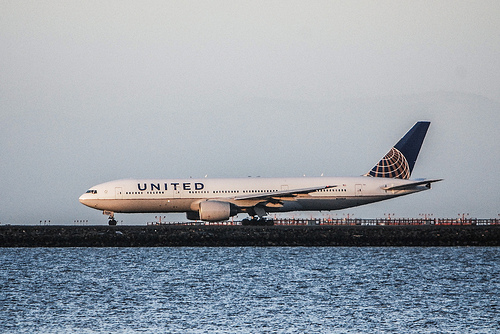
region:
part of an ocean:
[323, 152, 338, 169]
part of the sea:
[230, 249, 240, 255]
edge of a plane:
[401, 118, 414, 146]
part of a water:
[293, 268, 303, 297]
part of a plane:
[272, 113, 295, 198]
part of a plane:
[335, 200, 344, 205]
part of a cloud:
[281, 105, 290, 124]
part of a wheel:
[195, 189, 200, 205]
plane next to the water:
[33, 78, 476, 293]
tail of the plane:
[351, 97, 446, 192]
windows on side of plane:
[120, 182, 176, 202]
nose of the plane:
[65, 172, 120, 227]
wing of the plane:
[215, 157, 345, 244]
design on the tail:
[351, 106, 437, 188]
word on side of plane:
[125, 167, 215, 199]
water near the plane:
[135, 251, 238, 317]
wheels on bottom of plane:
[236, 206, 282, 232]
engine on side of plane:
[185, 187, 244, 234]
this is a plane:
[19, 25, 490, 293]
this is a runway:
[14, 95, 326, 257]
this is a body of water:
[111, 250, 338, 320]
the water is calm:
[89, 254, 226, 302]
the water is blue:
[84, 251, 244, 296]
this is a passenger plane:
[76, 165, 363, 214]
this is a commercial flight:
[85, 107, 373, 232]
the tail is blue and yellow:
[366, 109, 448, 177]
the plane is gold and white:
[103, 157, 383, 297]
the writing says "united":
[106, 159, 224, 196]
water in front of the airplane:
[8, 248, 461, 331]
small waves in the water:
[248, 254, 309, 308]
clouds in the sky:
[5, 62, 314, 144]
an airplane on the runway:
[81, 117, 450, 219]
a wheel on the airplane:
[107, 215, 115, 222]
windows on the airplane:
[126, 187, 176, 196]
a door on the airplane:
[114, 187, 119, 199]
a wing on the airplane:
[242, 178, 333, 197]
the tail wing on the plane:
[365, 113, 431, 173]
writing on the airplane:
[131, 180, 207, 188]